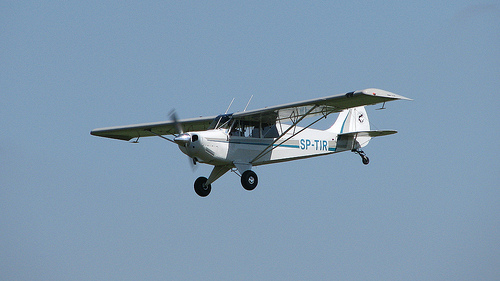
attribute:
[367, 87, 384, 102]
light — red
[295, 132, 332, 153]
writing — blue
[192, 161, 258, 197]
gear — landing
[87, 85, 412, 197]
plane — little, white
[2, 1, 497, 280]
sky — blue, cloudless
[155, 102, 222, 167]
propeller — spinning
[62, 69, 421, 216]
airplane — white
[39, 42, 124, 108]
sky — cloudless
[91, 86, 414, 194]
airplane — white, blue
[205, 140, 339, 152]
stripe — gray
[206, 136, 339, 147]
stripe — blue, gray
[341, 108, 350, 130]
stripe — blue, gray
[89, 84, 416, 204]
airplane — white 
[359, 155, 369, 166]
tire — small, black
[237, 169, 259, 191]
tire — small, black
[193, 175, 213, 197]
tire — small, black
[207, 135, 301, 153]
stripes — gray, blue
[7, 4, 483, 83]
sky — blue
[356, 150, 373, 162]
wheel — small